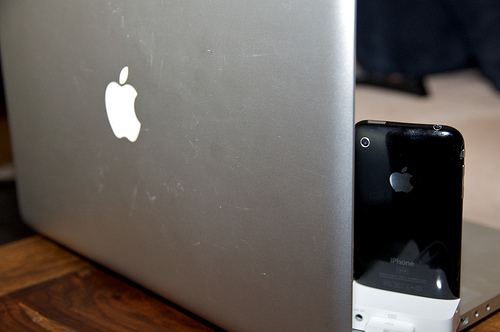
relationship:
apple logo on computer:
[104, 66, 140, 143] [14, 7, 404, 319]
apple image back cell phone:
[389, 167, 414, 193] [353, 118, 467, 300]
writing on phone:
[389, 255, 416, 268] [352, 122, 464, 329]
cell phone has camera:
[350, 108, 467, 331] [354, 131, 376, 158]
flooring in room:
[361, 70, 498, 226] [2, 1, 499, 328]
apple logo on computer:
[104, 66, 140, 143] [1, 1, 498, 330]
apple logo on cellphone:
[104, 66, 140, 143] [355, 118, 467, 302]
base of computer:
[359, 218, 499, 321] [1, 1, 498, 330]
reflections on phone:
[351, 118, 463, 298] [352, 122, 464, 329]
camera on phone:
[359, 137, 371, 150] [352, 120, 464, 300]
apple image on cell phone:
[385, 160, 420, 198] [353, 118, 467, 300]